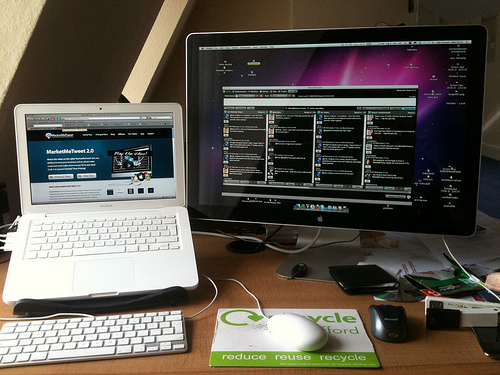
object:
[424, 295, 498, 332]
stapler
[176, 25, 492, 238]
monitor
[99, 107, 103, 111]
camera lens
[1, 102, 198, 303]
laptop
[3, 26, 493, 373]
workstation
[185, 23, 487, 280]
computer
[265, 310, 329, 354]
mouse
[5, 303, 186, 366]
keyboard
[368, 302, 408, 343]
mouse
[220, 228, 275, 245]
cords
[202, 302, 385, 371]
mousepad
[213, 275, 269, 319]
white cord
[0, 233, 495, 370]
desk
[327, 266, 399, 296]
wallet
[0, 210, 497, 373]
table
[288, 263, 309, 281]
clock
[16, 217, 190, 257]
keyboard